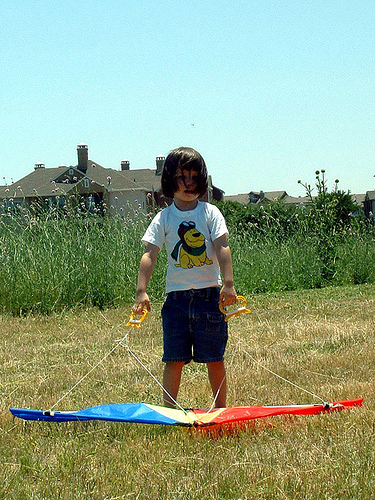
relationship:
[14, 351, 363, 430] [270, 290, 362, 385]
kite on ground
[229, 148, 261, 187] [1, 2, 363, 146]
cloud in sky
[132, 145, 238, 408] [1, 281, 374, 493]
child in field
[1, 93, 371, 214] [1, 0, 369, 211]
clouds are in sky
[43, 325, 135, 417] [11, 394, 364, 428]
rope on kite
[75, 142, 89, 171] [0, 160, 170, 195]
chimney on roof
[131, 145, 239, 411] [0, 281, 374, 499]
child standing on grass